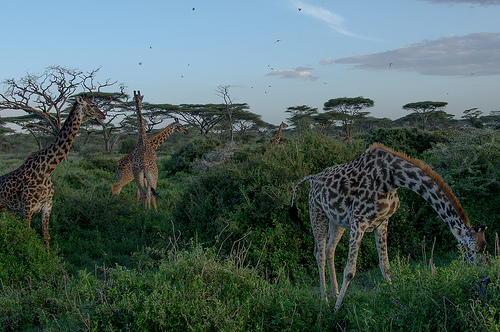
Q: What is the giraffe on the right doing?
A: Bending to eat.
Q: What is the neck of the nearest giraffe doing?
A: Bending.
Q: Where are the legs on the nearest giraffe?
A: On the grass.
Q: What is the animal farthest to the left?
A: A giraffe.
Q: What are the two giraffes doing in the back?
A: Standing next to each other.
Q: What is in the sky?
A: Clouds.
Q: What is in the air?
A: Birds.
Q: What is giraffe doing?
A: Grazing.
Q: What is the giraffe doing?
A: Standing.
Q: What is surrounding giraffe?
A: Bush.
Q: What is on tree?
A: Branches.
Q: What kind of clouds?
A: Fluffy.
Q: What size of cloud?
A: Large.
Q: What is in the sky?
A: Clouds.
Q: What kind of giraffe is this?
A: A giraffe with spots.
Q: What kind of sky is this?
A: A light blue sky.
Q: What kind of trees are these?
A: Dark green trees.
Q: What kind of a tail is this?
A: A giraffe tail.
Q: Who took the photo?
A: Jackson Mingus.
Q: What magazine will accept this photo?
A: National Geographic.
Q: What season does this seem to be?
A: Summer.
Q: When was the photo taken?
A: Daytime.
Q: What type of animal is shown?
A: Giraffe.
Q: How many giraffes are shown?
A: Five.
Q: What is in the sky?
A: Clouds.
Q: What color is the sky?
A: Blue.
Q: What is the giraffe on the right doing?
A: Eating.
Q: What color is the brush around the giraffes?
A: Green.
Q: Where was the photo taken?
A: At a safari.